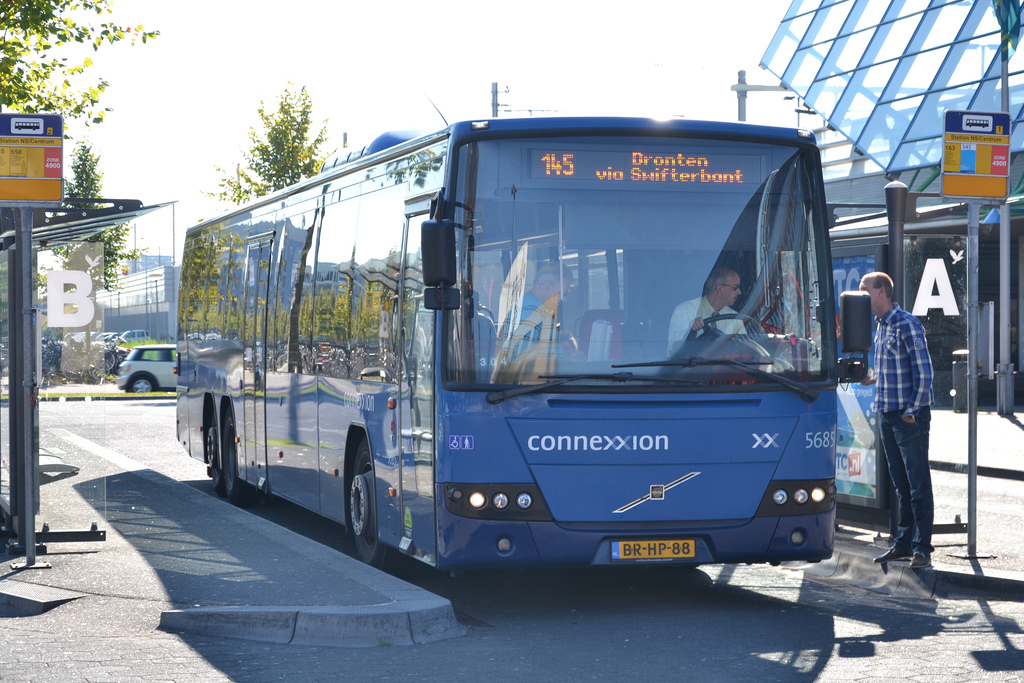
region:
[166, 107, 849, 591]
Blue bus with yellow licence plate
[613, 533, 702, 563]
Yellow rectangular licence plate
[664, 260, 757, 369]
Driver inside the bus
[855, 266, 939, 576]
Guy standing next to the blue bus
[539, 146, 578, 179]
number printed on the blus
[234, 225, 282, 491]
door of the bus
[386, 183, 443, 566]
Door of the bus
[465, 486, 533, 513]
three lights on the front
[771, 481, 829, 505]
Three lights on the bus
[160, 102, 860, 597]
a blue bus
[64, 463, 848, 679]
shadow of the bus on the street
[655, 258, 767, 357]
a man driving a bus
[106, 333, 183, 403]
a parked white car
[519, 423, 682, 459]
word on the front of the bus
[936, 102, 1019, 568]
a sign and a post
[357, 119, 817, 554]
a blue bus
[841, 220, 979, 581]
a man talking to the bus driver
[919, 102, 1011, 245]
a bus stop sing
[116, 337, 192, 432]
a white car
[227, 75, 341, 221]
green tree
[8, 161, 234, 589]
a bus stop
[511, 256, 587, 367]
people on the bus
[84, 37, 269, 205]
a blue sky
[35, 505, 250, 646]
gray walkway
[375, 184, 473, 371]
side view merrow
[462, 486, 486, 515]
Light on a bus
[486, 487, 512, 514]
Light on a bus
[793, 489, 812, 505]
Light on a bus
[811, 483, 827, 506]
Light on a bus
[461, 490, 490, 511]
Light on a blue bus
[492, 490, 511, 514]
Light on a blue bus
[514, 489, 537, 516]
Light on a blue bus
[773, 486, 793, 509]
Light on a blue bus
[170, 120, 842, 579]
a large blue bus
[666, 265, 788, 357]
the bus driver is wearing a white shirt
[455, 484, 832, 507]
two illuminated lights on the front of the bus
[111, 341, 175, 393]
a silver color vehicle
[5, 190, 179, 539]
a bus stop with clear sides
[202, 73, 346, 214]
a tall green tree behind the bus